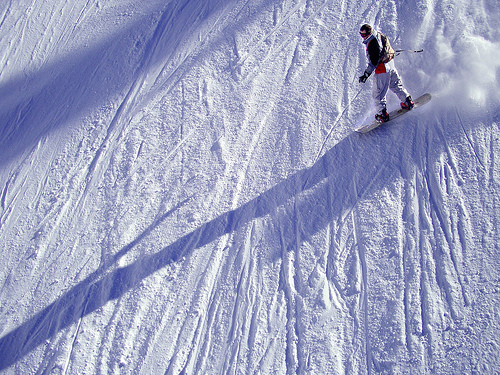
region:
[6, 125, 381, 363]
A shadow on the snow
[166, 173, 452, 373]
A trail already in the snow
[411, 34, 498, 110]
Dust from the snow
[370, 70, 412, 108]
The snowboarder has white pants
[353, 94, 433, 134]
The snowboard on the snow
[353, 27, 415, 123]
A person on a snowboard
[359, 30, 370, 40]
The person is wearing goggles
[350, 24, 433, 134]
A person is snowboarding down the hill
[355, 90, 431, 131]
The snowboard is going down the hill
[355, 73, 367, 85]
The left hand of the person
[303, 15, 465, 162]
a man is snowboarding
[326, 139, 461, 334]
lines are in the snow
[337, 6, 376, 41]
man is wearing goggles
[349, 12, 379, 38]
man has brown hair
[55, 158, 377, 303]
shadow on the snow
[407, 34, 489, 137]
the snow is fluffy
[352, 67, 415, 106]
the pants are grey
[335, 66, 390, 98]
man is wearing gloves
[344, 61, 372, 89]
the gloves are black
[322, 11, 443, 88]
the coat is black and grey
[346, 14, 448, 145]
This is a person skiing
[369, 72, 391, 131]
Leg of a skiing person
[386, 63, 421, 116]
Leg of a skiing person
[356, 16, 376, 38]
Head of a skiing person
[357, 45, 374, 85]
Hand of a skiing person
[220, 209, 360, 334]
This is ice for skiing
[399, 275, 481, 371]
This is ice for skiing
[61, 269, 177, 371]
This is ice for skiing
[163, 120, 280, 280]
This is ice for skiing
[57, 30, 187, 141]
this is the ground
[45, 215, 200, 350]
the ground is full of snow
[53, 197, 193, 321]
this is the snow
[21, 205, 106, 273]
the snow is white in color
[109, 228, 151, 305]
this is a shadow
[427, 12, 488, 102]
this is some snow dust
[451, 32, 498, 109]
the dust is white in color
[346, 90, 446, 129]
this is a snowboard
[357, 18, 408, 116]
this is a man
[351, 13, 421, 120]
the man is on the snowboard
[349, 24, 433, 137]
snowboarder going down a slope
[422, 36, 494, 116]
cloud of snow dust behind the snow boarder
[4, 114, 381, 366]
shadow casted from the snow boarder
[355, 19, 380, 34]
helmet on the snowboarder's head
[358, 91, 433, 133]
snow board under the man's feet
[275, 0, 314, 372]
track in the snow from snow boarders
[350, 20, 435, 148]
man on a snowboard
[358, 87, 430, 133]
snow board being ridden by a man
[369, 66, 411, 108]
white pants on the man's feet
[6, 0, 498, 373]
fresh snow on the ground